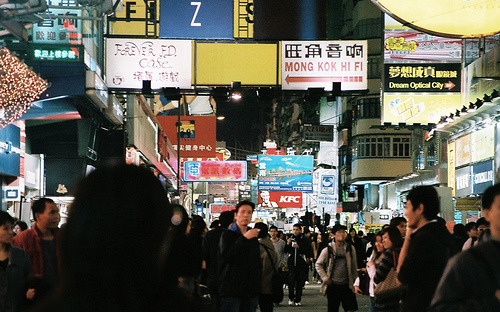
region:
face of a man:
[244, 195, 264, 222]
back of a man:
[426, 245, 452, 251]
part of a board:
[211, 68, 225, 97]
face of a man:
[238, 209, 253, 234]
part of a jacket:
[329, 240, 347, 273]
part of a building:
[365, 154, 372, 175]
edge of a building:
[355, 122, 385, 172]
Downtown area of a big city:
[100, 65, 485, 295]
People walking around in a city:
[76, 118, 488, 296]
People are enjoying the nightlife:
[95, 105, 485, 300]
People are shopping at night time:
[95, 126, 476, 306]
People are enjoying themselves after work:
[15, 31, 468, 299]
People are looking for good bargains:
[45, 62, 490, 307]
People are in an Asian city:
[65, 50, 482, 298]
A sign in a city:
[280, 33, 370, 90]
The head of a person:
[233, 197, 253, 227]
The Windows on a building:
[360, 133, 405, 158]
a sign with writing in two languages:
[280, 40, 366, 95]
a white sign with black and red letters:
[280, 33, 369, 93]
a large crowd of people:
[0, 165, 499, 306]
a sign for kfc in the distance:
[255, 190, 303, 207]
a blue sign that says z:
[158, 0, 233, 37]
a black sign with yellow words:
[382, 61, 464, 93]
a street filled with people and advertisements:
[0, 0, 499, 310]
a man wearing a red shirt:
[10, 195, 69, 305]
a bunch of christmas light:
[0, 44, 52, 126]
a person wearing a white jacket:
[315, 219, 361, 309]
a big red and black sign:
[278, 33, 380, 89]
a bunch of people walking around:
[0, 172, 477, 306]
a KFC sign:
[253, 185, 306, 211]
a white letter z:
[179, 3, 221, 31]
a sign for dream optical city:
[379, 56, 469, 98]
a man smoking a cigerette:
[316, 220, 370, 310]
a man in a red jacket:
[8, 196, 71, 286]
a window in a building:
[379, 133, 394, 158]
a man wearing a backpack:
[313, 217, 360, 309]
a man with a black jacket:
[217, 200, 266, 310]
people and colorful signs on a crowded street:
[16, 10, 487, 295]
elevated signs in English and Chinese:
[96, 31, 366, 211]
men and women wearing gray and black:
[0, 160, 491, 300]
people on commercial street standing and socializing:
[5, 170, 492, 305]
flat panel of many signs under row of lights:
[444, 88, 495, 194]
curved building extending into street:
[347, 15, 415, 185]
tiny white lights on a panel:
[0, 36, 45, 126]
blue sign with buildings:
[250, 150, 312, 190]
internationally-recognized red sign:
[251, 186, 301, 206]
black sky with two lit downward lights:
[216, 87, 266, 144]